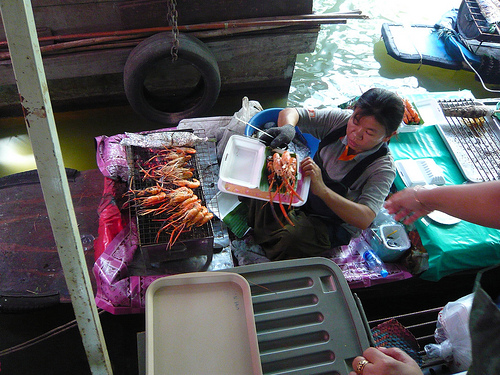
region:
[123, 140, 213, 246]
the craw on the grill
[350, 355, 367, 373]
the ruing on the finger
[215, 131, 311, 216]
the fish in the container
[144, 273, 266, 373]
the white tray by the hand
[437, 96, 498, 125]
the meat on the grill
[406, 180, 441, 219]
the bracelet on the wrist of the person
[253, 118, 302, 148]
the glove on the hand of the person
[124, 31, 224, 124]
the black tire hanging over the water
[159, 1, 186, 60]
the chain on the tire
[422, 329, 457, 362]
the knot in the palstic bag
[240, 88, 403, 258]
the woman sitting down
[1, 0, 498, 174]
the green water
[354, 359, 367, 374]
the rings on the finger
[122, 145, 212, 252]
the pile of seafood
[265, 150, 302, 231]
the seafood in the styrofoam container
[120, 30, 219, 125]
the black tire hanging from a chain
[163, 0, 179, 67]
the chain hanging the black tire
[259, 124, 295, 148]
the glove on the woman's hand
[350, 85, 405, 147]
the dark hair on the woman's head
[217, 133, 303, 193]
the white styrofoam container holding the seafood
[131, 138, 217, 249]
a few shrimp on a grill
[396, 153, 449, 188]
a white togo box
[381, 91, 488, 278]
a pale green tarp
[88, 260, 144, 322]
a purple bandanna print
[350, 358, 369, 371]
a gold wedding band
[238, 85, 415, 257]
a woman in a black apron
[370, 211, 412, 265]
a pale colored container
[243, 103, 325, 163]
a blue plastic bucket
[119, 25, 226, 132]
an old tire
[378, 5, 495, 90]
a floating contraption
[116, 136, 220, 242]
A grill with large shrimp cooking on it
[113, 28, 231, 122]
Old tire hanging from a chain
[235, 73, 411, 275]
Woman selling shrimp from her boat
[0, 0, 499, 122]
Boats floating the the water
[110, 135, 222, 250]
Large fresh shrimp being prepared to sell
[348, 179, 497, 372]
Customer waiting to buy fresh seafood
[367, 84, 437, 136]
Celery and carrots on a tray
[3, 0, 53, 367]
Support pole for riverside dock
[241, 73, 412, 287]
Woman selling seafood wearing a glove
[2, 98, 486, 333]
Boat floating in a dirty green river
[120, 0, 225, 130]
Tire hanging from chain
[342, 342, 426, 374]
Person's hand with gold ring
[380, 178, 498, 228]
Person's arm with gold bracelet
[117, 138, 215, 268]
Seafood on barbecue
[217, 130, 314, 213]
Food in styrofoam container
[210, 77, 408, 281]
Woman holding Styrofoam container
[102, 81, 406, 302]
Woman preparing seafood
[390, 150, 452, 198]
White Styrofoam container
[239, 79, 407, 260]
Woman with black hair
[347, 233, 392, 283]
Clear plastic water bottle